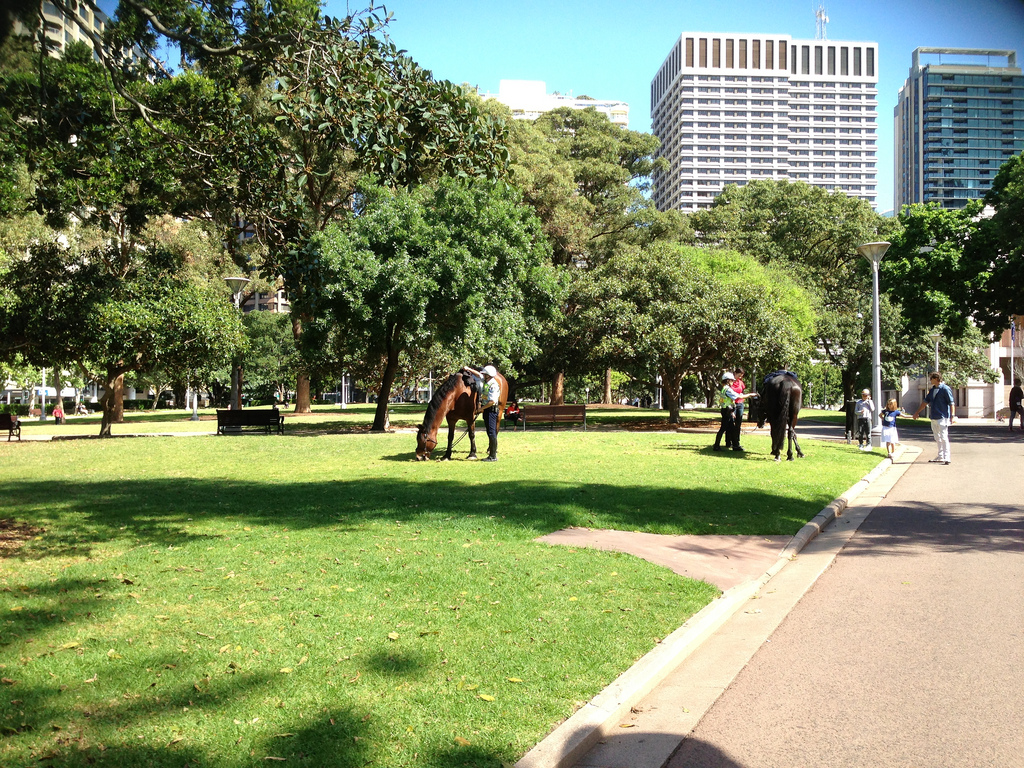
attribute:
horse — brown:
[411, 371, 514, 461]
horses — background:
[411, 364, 809, 469]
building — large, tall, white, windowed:
[649, 30, 879, 421]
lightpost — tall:
[852, 234, 895, 430]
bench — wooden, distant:
[215, 402, 285, 436]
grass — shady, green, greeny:
[0, 402, 896, 768]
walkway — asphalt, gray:
[665, 416, 1022, 767]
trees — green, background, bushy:
[0, 0, 1022, 437]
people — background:
[2, 379, 206, 439]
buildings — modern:
[649, 31, 1022, 417]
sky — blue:
[94, 1, 1022, 217]